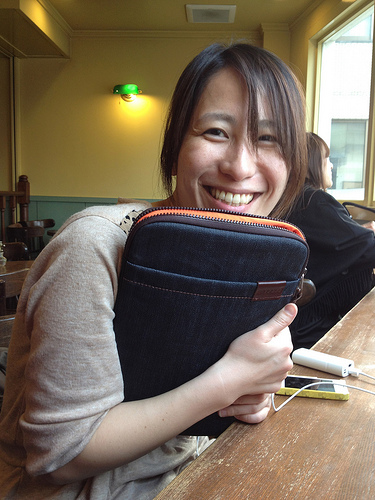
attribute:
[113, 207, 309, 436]
tablet case — denim, blue, protective, held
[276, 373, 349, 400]
cellphone — white, yellow, present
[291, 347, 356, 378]
charger — white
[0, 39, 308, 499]
woman — smiling, sitting, asian descent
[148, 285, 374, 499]
table — brown, wooden, worn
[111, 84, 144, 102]
light — green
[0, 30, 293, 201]
wall — yellow, painted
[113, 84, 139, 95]
shade — hooded, green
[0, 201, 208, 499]
blouse — light brown, gray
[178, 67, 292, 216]
face — smiling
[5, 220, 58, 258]
chair — brown, wooden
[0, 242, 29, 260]
chair — wooden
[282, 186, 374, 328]
poncho — black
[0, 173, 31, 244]
rail — wooden, brown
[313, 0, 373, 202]
window — present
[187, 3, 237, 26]
vent — white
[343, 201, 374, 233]
bag — blue, orange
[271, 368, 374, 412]
cord — white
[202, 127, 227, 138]
eye — brown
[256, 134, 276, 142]
eye — brown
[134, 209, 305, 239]
lining — orange